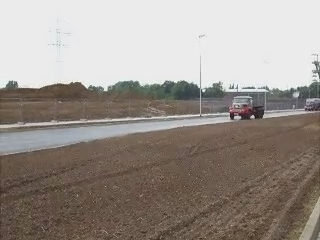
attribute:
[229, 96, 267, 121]
truck — red, driving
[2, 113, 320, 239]
dirt — brown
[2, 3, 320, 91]
sky — gray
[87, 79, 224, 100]
trees — green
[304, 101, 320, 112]
truck — dark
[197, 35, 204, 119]
pole — tall, gray, metal, slender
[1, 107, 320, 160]
pavement — black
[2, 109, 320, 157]
road — smooth, gray, paved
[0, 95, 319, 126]
fence — metal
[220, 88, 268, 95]
top — white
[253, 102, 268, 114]
bed — flat